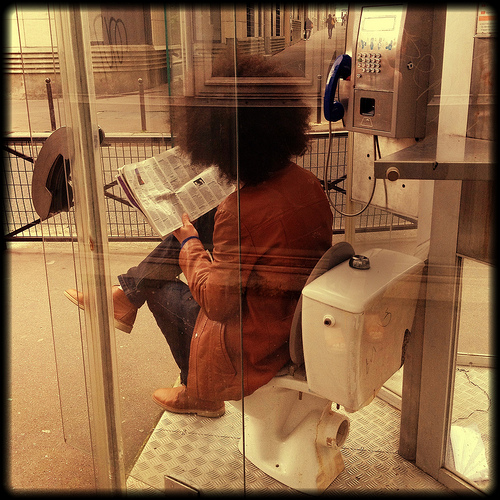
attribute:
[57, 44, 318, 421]
lady — here, fully dressed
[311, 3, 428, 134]
phone — silver, grey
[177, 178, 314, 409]
pullover — brown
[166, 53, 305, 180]
hair — long, black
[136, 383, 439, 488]
floor — stone, diamond pattern, metal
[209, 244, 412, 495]
toilet — disconnected, white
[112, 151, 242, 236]
newspaper — white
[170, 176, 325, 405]
jacket — brown, long, leather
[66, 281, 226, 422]
boots — brown, ankle length, on feet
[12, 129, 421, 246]
fence — metal, silver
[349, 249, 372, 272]
knob — silver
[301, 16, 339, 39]
people — walking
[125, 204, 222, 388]
jeans — blue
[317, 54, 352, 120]
phone receiver — blue